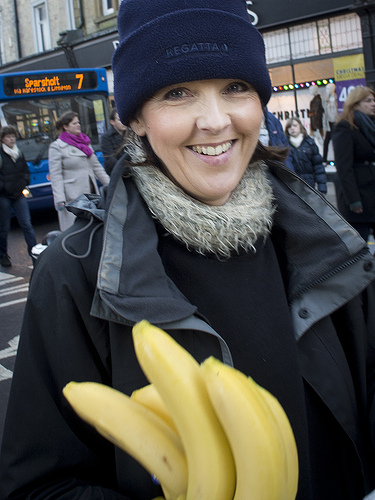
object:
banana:
[62, 379, 189, 500]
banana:
[200, 355, 289, 500]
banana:
[132, 318, 237, 500]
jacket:
[0, 150, 375, 500]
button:
[299, 307, 310, 319]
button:
[363, 260, 372, 272]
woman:
[0, 16, 375, 500]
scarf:
[124, 132, 279, 262]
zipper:
[288, 171, 375, 343]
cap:
[111, 0, 274, 127]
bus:
[0, 66, 113, 211]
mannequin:
[322, 83, 339, 167]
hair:
[333, 84, 375, 129]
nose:
[196, 95, 232, 136]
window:
[30, 1, 53, 55]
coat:
[332, 109, 375, 244]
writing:
[166, 43, 230, 59]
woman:
[48, 109, 112, 234]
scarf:
[58, 129, 93, 157]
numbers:
[75, 74, 83, 89]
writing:
[14, 75, 72, 94]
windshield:
[32, 136, 51, 166]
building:
[257, 0, 375, 184]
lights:
[272, 78, 334, 93]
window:
[94, 0, 118, 24]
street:
[0, 268, 34, 438]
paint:
[0, 271, 29, 382]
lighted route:
[14, 74, 84, 95]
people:
[0, 124, 39, 268]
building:
[1, 0, 128, 71]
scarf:
[2, 143, 22, 163]